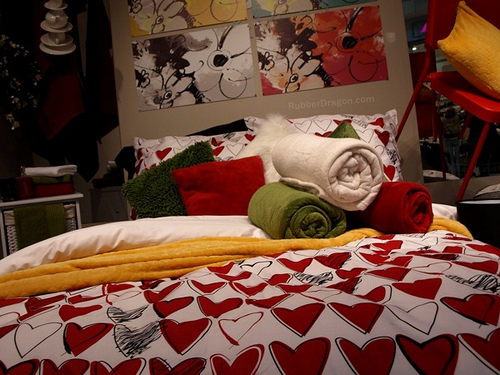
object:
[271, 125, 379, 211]
blanket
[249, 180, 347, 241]
blanket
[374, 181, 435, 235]
blanket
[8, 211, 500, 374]
blanket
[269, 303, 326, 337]
heart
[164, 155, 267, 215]
pillow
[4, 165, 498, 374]
bed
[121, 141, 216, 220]
pillow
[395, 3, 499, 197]
chair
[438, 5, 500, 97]
pillow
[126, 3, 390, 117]
picture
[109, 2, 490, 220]
wall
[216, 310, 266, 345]
heart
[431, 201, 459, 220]
sheet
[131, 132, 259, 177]
pillow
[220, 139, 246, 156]
heart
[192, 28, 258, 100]
flower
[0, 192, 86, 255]
table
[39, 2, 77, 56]
light fixture